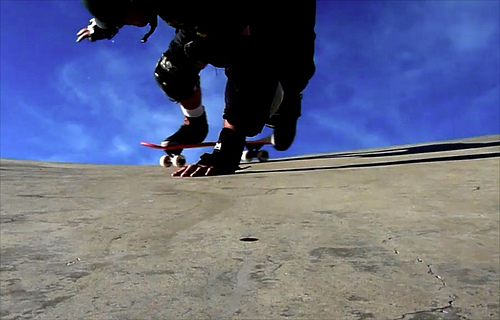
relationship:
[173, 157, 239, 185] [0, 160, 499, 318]
hand on ground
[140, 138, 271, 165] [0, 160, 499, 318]
skateboard on ground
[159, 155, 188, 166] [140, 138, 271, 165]
2 wheels on skateboard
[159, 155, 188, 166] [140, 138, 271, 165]
2 wheels on front skateboard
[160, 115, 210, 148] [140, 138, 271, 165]
foot on skateboard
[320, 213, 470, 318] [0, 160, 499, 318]
crack in pavement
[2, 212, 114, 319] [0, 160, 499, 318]
crack in pavement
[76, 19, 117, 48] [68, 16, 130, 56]
hand in air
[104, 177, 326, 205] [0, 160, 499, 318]
pebbles on ground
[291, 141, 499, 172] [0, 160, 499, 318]
shadow on ground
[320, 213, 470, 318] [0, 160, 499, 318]
crack on ground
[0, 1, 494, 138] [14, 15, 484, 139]
blue sky with clouds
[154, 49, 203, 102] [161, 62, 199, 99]
knee pad on knee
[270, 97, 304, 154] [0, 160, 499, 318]
foot off ground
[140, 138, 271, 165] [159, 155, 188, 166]
skateboard with 2 wheels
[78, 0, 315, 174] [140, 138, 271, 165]
person on skateboard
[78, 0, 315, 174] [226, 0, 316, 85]
person dressed black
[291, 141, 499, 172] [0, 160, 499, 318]
shadow on pavement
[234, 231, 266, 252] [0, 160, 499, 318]
spot on ground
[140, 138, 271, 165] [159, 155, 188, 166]
skateboard has 2 wheels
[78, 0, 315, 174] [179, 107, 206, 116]
skateboarder has white socks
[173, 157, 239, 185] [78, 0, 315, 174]
hand of person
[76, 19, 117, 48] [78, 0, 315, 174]
right hand of person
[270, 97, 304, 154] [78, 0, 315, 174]
left foot of person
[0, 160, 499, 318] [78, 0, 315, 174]
asphalt wall with person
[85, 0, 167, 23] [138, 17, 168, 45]
helmet with chin strap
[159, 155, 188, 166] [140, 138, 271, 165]
2 wheels of skateboard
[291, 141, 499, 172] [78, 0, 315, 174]
shadow of person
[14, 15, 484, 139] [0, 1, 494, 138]
clouds in sky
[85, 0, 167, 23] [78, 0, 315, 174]
helmet of person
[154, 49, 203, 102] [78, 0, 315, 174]
kneepad of person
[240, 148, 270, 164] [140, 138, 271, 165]
back wheels of skateboard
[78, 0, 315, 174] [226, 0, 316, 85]
person in black